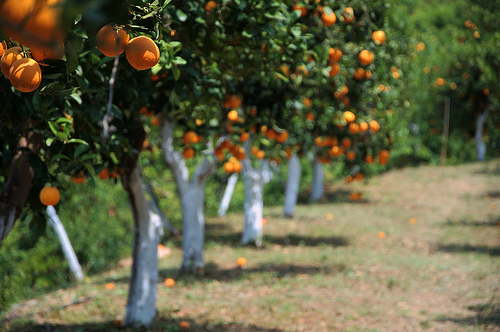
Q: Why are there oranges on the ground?
A: They fall off limb.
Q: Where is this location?
A: Orchard.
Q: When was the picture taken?
A: Daytime.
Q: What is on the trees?
A: Oranges.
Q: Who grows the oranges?
A: Farmer.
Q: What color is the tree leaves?
A: Green.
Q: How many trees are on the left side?
A: Five.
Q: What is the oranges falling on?
A: Grass.